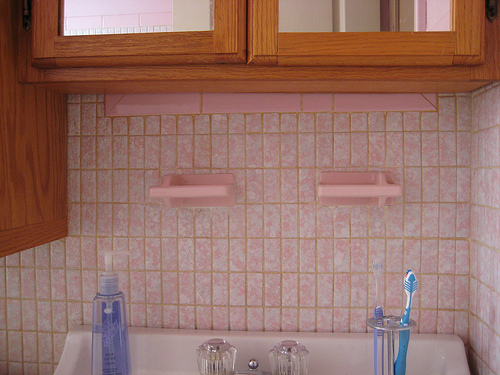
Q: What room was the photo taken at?
A: It was taken at the bathroom.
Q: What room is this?
A: It is a bathroom.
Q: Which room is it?
A: It is a bathroom.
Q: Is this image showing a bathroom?
A: Yes, it is showing a bathroom.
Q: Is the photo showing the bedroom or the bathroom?
A: It is showing the bathroom.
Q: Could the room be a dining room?
A: No, it is a bathroom.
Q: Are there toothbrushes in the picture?
A: Yes, there is a toothbrush.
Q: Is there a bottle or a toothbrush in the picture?
A: Yes, there is a toothbrush.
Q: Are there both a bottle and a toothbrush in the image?
A: Yes, there are both a toothbrush and a bottle.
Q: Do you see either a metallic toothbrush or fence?
A: Yes, there is a metal toothbrush.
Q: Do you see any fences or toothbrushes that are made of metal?
A: Yes, the toothbrush is made of metal.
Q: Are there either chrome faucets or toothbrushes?
A: Yes, there is a chrome toothbrush.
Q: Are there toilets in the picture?
A: No, there are no toilets.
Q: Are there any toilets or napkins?
A: No, there are no toilets or napkins.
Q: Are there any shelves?
A: No, there are no shelves.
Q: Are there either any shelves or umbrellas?
A: No, there are no shelves or umbrellas.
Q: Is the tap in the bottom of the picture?
A: Yes, the tap is in the bottom of the image.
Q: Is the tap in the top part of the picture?
A: No, the tap is in the bottom of the image.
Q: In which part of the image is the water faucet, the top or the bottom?
A: The tap is in the bottom of the image.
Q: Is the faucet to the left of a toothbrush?
A: Yes, the faucet is to the left of a toothbrush.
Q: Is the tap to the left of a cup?
A: No, the tap is to the left of a toothbrush.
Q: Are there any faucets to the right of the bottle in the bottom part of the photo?
A: Yes, there is a faucet to the right of the bottle.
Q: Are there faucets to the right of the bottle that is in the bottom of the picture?
A: Yes, there is a faucet to the right of the bottle.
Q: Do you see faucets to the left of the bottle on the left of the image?
A: No, the faucet is to the right of the bottle.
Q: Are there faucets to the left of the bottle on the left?
A: No, the faucet is to the right of the bottle.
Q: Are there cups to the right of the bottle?
A: No, there is a faucet to the right of the bottle.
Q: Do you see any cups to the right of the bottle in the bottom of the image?
A: No, there is a faucet to the right of the bottle.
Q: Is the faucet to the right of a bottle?
A: Yes, the faucet is to the right of a bottle.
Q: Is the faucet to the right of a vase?
A: No, the faucet is to the right of a bottle.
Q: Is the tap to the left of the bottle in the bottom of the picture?
A: No, the tap is to the right of the bottle.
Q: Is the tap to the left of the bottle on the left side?
A: No, the tap is to the right of the bottle.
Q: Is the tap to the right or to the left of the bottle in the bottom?
A: The tap is to the right of the bottle.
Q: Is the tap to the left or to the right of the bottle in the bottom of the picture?
A: The tap is to the right of the bottle.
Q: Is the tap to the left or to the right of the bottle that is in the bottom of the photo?
A: The tap is to the right of the bottle.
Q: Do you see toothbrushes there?
A: Yes, there is a toothbrush.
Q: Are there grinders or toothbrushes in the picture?
A: Yes, there is a toothbrush.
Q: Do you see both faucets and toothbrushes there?
A: Yes, there are both a toothbrush and a faucet.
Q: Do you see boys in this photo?
A: No, there are no boys.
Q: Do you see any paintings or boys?
A: No, there are no boys or paintings.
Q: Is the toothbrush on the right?
A: Yes, the toothbrush is on the right of the image.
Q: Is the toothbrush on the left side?
A: No, the toothbrush is on the right of the image.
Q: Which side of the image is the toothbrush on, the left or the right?
A: The toothbrush is on the right of the image.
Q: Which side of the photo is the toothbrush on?
A: The toothbrush is on the right of the image.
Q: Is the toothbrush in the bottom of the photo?
A: Yes, the toothbrush is in the bottom of the image.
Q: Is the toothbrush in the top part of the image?
A: No, the toothbrush is in the bottom of the image.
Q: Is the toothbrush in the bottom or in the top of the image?
A: The toothbrush is in the bottom of the image.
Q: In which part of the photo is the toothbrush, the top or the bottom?
A: The toothbrush is in the bottom of the image.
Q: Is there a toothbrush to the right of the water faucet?
A: Yes, there is a toothbrush to the right of the tap.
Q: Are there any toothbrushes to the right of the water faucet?
A: Yes, there is a toothbrush to the right of the tap.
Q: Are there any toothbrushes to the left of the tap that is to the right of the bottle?
A: No, the toothbrush is to the right of the tap.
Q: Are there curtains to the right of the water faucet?
A: No, there is a toothbrush to the right of the tap.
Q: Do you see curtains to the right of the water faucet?
A: No, there is a toothbrush to the right of the tap.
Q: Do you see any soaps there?
A: Yes, there is a soap.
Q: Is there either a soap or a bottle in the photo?
A: Yes, there is a soap.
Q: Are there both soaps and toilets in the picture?
A: No, there is a soap but no toilets.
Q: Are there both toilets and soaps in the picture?
A: No, there is a soap but no toilets.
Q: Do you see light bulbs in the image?
A: No, there are no light bulbs.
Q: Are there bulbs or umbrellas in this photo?
A: No, there are no bulbs or umbrellas.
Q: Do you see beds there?
A: No, there are no beds.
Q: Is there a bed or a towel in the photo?
A: No, there are no beds or towels.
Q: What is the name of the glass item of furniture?
A: The piece of furniture is a cupboard.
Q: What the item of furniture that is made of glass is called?
A: The piece of furniture is a cupboard.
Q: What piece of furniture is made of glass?
A: The piece of furniture is a cupboard.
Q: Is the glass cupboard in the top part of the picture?
A: Yes, the cupboard is in the top of the image.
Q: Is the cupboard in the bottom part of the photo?
A: No, the cupboard is in the top of the image.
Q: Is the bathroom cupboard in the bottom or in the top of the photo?
A: The cupboard is in the top of the image.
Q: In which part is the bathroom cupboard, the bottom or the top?
A: The cupboard is in the top of the image.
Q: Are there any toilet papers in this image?
A: No, there are no toilet papers.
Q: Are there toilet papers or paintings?
A: No, there are no toilet papers or paintings.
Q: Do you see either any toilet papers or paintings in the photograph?
A: No, there are no toilet papers or paintings.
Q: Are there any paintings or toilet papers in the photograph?
A: No, there are no toilet papers or paintings.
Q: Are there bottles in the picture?
A: Yes, there is a bottle.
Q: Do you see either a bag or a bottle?
A: Yes, there is a bottle.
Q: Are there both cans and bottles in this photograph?
A: No, there is a bottle but no cans.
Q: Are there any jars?
A: No, there are no jars.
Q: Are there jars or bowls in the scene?
A: No, there are no jars or bowls.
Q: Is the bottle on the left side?
A: Yes, the bottle is on the left of the image.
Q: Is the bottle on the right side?
A: No, the bottle is on the left of the image.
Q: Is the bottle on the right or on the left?
A: The bottle is on the left of the image.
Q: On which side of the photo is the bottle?
A: The bottle is on the left of the image.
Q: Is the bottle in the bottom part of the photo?
A: Yes, the bottle is in the bottom of the image.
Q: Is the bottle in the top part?
A: No, the bottle is in the bottom of the image.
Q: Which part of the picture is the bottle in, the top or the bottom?
A: The bottle is in the bottom of the image.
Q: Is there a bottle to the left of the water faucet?
A: Yes, there is a bottle to the left of the tap.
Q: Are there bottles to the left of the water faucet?
A: Yes, there is a bottle to the left of the tap.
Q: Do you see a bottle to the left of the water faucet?
A: Yes, there is a bottle to the left of the tap.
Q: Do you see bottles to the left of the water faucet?
A: Yes, there is a bottle to the left of the tap.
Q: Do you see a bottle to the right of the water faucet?
A: No, the bottle is to the left of the faucet.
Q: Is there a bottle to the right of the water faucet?
A: No, the bottle is to the left of the faucet.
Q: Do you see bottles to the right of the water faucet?
A: No, the bottle is to the left of the faucet.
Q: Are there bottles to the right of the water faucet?
A: No, the bottle is to the left of the faucet.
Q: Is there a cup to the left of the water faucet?
A: No, there is a bottle to the left of the faucet.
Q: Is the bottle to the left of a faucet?
A: Yes, the bottle is to the left of a faucet.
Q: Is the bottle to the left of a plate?
A: No, the bottle is to the left of a faucet.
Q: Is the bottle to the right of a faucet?
A: No, the bottle is to the left of a faucet.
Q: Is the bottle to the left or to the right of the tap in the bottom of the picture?
A: The bottle is to the left of the tap.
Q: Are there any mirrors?
A: Yes, there is a mirror.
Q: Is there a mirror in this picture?
A: Yes, there is a mirror.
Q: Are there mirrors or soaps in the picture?
A: Yes, there is a mirror.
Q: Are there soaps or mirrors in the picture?
A: Yes, there is a mirror.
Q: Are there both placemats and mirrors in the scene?
A: No, there is a mirror but no placemats.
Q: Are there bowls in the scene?
A: No, there are no bowls.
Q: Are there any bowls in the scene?
A: No, there are no bowls.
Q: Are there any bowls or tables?
A: No, there are no bowls or tables.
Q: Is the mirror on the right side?
A: Yes, the mirror is on the right of the image.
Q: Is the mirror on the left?
A: No, the mirror is on the right of the image.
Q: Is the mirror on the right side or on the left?
A: The mirror is on the right of the image.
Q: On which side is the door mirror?
A: The mirror is on the right of the image.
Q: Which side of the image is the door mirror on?
A: The mirror is on the right of the image.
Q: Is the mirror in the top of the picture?
A: Yes, the mirror is in the top of the image.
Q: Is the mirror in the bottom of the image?
A: No, the mirror is in the top of the image.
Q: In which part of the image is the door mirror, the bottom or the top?
A: The mirror is in the top of the image.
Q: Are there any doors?
A: Yes, there is a door.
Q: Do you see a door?
A: Yes, there is a door.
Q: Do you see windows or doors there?
A: Yes, there is a door.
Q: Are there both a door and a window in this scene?
A: No, there is a door but no windows.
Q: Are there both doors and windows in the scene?
A: No, there is a door but no windows.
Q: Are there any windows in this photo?
A: No, there are no windows.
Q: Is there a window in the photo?
A: No, there are no windows.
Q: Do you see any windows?
A: No, there are no windows.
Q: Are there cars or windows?
A: No, there are no windows or cars.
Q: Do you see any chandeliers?
A: No, there are no chandeliers.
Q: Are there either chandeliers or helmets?
A: No, there are no chandeliers or helmets.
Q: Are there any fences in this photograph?
A: No, there are no fences.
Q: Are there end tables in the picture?
A: No, there are no end tables.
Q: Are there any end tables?
A: No, there are no end tables.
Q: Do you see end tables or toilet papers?
A: No, there are no end tables or toilet papers.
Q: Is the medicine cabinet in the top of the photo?
A: Yes, the medicine cabinet is in the top of the image.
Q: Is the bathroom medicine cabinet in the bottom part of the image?
A: No, the medicine cabinet is in the top of the image.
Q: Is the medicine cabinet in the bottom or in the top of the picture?
A: The medicine cabinet is in the top of the image.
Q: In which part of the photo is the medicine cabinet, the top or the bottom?
A: The medicine cabinet is in the top of the image.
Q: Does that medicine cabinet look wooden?
A: Yes, the medicine cabinet is wooden.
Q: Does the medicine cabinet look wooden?
A: Yes, the medicine cabinet is wooden.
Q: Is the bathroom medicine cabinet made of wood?
A: Yes, the medicine cabinet is made of wood.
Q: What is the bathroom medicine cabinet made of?
A: The medicine cabinet is made of wood.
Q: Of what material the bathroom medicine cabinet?
A: The medicine cabinet is made of wood.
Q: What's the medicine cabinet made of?
A: The medicine cabinet is made of wood.